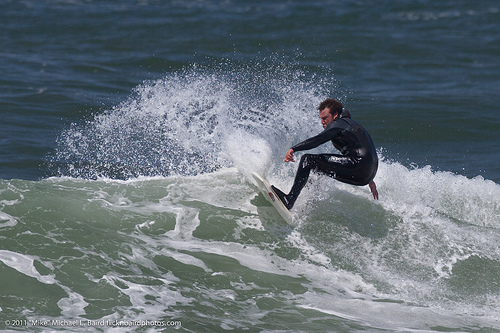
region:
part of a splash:
[233, 99, 273, 177]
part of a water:
[276, 271, 323, 320]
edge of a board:
[250, 179, 285, 226]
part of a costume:
[354, 144, 374, 167]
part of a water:
[413, 95, 460, 162]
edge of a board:
[263, 189, 293, 211]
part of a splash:
[192, 86, 232, 126]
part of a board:
[267, 183, 304, 242]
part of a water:
[396, 90, 442, 151]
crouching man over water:
[275, 100, 376, 201]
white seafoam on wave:
[0, 179, 260, 329]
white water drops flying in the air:
[56, 65, 313, 182]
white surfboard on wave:
[253, 174, 299, 231]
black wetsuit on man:
[273, 117, 373, 207]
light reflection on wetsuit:
[323, 152, 359, 167]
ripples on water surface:
[3, 36, 496, 158]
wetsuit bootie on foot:
[271, 184, 296, 214]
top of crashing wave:
[392, 207, 495, 296]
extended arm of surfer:
[285, 122, 337, 152]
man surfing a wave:
[237, 83, 413, 245]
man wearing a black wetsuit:
[247, 75, 390, 230]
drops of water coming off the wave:
[36, 58, 311, 174]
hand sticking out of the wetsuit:
[282, 149, 301, 164]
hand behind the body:
[364, 182, 381, 202]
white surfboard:
[242, 168, 304, 227]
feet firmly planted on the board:
[268, 174, 293, 211]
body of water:
[2, 2, 494, 332]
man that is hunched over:
[268, 96, 390, 211]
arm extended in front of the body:
[269, 123, 347, 165]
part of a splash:
[219, 115, 266, 189]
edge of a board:
[264, 178, 309, 245]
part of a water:
[223, 268, 258, 318]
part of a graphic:
[143, 309, 174, 326]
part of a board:
[275, 193, 298, 230]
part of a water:
[159, 258, 202, 293]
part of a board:
[259, 185, 286, 207]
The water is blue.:
[0, 0, 499, 182]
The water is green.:
[0, 178, 497, 328]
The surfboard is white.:
[246, 168, 294, 223]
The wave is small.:
[1, 173, 498, 332]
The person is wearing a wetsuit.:
[269, 95, 382, 215]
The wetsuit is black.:
[266, 94, 382, 214]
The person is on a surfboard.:
[246, 95, 383, 222]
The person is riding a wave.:
[247, 95, 383, 225]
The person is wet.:
[249, 97, 386, 228]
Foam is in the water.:
[1, 181, 498, 330]